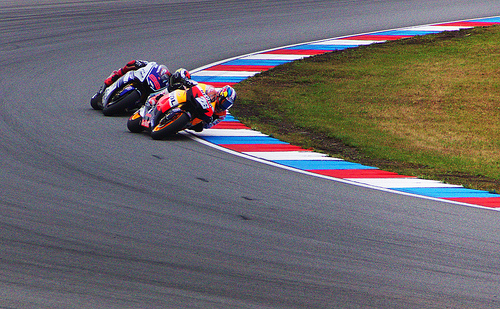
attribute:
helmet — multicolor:
[218, 83, 243, 113]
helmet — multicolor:
[165, 62, 195, 92]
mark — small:
[193, 171, 212, 188]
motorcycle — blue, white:
[90, 60, 169, 115]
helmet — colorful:
[216, 83, 237, 108]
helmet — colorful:
[168, 68, 188, 84]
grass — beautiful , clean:
[240, 25, 499, 177]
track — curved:
[4, 24, 399, 306]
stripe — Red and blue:
[319, 34, 387, 46]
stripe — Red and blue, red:
[183, 9, 495, 224]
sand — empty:
[367, 46, 496, 176]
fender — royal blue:
[117, 80, 142, 100]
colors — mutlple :
[183, 14, 498, 213]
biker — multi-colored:
[127, 82, 234, 137]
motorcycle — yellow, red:
[127, 82, 206, 152]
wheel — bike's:
[151, 118, 189, 135]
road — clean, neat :
[7, 115, 338, 306]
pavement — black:
[7, 0, 497, 302]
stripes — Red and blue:
[253, 137, 310, 177]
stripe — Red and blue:
[186, 13, 498, 210]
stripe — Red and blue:
[392, 184, 497, 199]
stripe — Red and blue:
[388, 182, 498, 208]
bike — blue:
[82, 50, 143, 118]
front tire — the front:
[104, 85, 136, 100]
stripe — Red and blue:
[202, 60, 276, 73]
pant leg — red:
[102, 60, 134, 84]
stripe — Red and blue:
[368, 30, 437, 37]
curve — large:
[50, 6, 498, 231]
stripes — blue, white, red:
[169, 13, 499, 214]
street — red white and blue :
[275, 146, 373, 180]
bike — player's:
[127, 83, 234, 137]